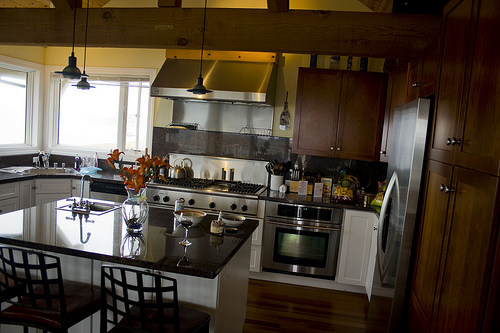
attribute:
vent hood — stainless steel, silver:
[151, 58, 277, 109]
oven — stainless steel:
[260, 201, 345, 280]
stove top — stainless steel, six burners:
[148, 173, 265, 197]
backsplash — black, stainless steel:
[151, 127, 291, 185]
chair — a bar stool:
[0, 247, 106, 332]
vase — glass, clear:
[122, 184, 149, 233]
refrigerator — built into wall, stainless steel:
[369, 97, 431, 331]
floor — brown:
[241, 279, 368, 331]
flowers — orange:
[107, 149, 170, 191]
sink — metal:
[65, 198, 120, 217]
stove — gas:
[142, 153, 266, 268]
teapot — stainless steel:
[168, 159, 188, 179]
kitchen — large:
[1, 0, 497, 332]